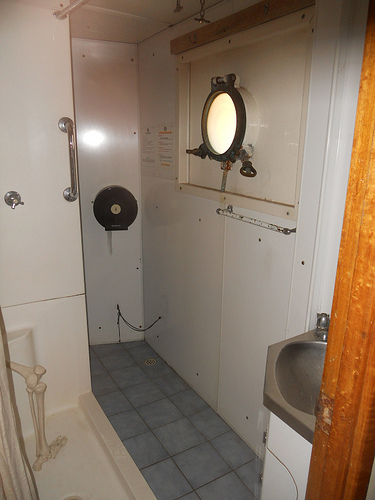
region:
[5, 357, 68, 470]
Skeleton leg sticking out of the shower.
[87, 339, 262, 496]
The bathroom floor is gray tile.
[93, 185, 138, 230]
Black toilet paper dispenser.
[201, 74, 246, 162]
Porthole to look outside.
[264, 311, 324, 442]
Stainless steel sink.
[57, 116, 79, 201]
Grab bar on the side of shower.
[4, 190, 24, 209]
Water turn nozzle on shower wall.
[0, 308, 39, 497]
The shower curtain is white.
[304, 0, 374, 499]
The door frame is made of wood.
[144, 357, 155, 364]
Drain on the tile floor.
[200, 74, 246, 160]
a circle shaped viewing window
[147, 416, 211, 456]
a blue porcelain tile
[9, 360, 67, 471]
a plastic skeleton leg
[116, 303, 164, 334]
a black cord stretched between two walls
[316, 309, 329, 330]
a silver metal knob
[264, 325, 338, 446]
a gray metal sink basin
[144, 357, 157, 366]
a metal bathroom drain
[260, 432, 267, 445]
a metal hinge on the front of a cabinet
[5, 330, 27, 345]
the plastic soap tray in a tub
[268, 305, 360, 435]
sink in the bathroom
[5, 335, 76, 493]
skeleton in the shower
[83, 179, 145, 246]
roll of tissue on the wall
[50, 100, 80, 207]
handrail on the wall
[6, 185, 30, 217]
Knob for water on the wall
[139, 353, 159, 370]
drain on the floor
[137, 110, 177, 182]
signs on the wall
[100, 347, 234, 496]
blue tiles on the floor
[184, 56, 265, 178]
window on the wall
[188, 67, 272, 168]
window on the wall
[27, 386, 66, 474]
a white skeletons leg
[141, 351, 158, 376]
a silver drain in the floor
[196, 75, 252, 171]
a port hole in the wall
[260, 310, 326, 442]
a silver sink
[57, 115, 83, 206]
a metal grip handle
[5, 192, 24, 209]
a knob on the wall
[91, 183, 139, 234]
a toilet paper holder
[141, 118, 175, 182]
a sign on the wall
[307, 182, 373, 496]
a wooden door frame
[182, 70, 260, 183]
porthole on white wall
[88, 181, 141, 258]
multi roll toilet paper dispenser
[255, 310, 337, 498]
edge of metal sink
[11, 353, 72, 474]
skeleton lower leg and foot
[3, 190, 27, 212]
water tap valve on wall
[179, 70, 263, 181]
round window with metal frame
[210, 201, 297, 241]
white towel bar with cracked paint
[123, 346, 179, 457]
grey tile floor with dark grout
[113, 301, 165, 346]
small chain hanging in corner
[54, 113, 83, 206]
metal safety hand hold